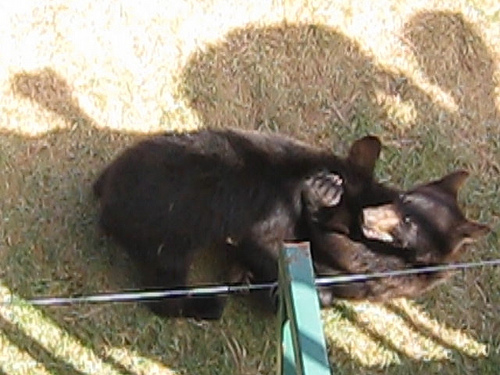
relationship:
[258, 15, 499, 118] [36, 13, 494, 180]
sunlight on grass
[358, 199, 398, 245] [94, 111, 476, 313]
snout on bear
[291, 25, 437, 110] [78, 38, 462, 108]
hay covering earth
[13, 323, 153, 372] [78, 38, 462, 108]
grass covering earth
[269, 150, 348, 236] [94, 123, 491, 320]
arms in bear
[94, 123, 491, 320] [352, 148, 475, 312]
bear with head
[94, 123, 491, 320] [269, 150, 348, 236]
bear with arms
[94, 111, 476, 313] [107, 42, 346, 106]
bear rolling hay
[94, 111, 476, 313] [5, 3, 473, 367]
bear in zoo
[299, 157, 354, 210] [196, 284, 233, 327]
claws on paw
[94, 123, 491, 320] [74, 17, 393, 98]
bear rolling ground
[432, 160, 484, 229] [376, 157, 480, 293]
ear on head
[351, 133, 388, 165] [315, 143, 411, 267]
ear on head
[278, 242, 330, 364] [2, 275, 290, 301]
pole on fence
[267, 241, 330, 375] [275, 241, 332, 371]
brace on fence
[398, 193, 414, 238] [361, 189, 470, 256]
eye in face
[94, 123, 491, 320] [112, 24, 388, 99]
bear wrestling ground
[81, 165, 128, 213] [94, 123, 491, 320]
tail on bear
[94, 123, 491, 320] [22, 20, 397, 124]
bear wrestling ground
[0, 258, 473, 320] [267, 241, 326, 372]
cable running brace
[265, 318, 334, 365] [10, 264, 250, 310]
structure under deck